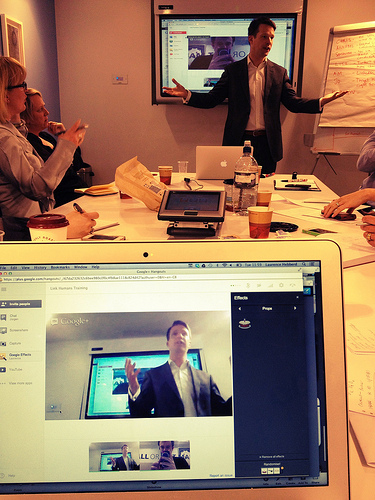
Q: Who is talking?
A: The man in the suit.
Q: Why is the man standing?
A: He is giving a presentation.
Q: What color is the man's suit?
A: Black.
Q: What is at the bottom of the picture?
A: A laptop screen.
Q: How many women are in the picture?
A: 2.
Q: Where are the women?
A: Sitting on the left.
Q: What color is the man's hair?
A: Dark brown.